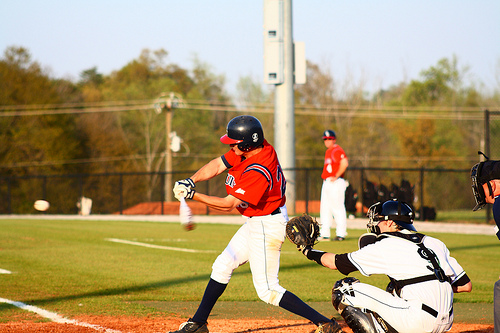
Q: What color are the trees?
A: Green.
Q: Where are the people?
A: On baseball field.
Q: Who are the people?
A: Baseball players.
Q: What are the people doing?
A: Playing baseball.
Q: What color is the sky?
A: Blue.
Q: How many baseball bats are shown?
A: One.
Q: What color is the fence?
A: Black.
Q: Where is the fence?
A: Around field.